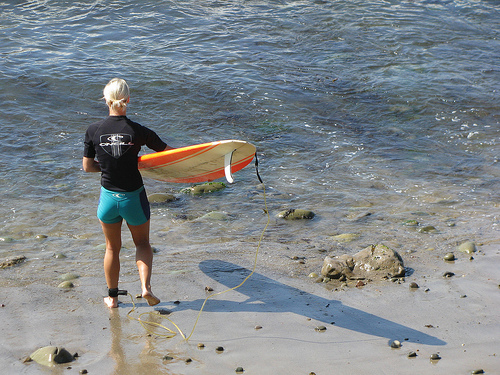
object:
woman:
[82, 78, 176, 308]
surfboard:
[137, 140, 257, 184]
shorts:
[96, 186, 152, 226]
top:
[85, 116, 170, 192]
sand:
[1, 180, 500, 374]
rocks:
[25, 342, 80, 369]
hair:
[100, 77, 131, 109]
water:
[1, 0, 498, 285]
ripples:
[0, 0, 500, 291]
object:
[106, 288, 128, 297]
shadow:
[118, 258, 446, 351]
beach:
[0, 189, 499, 373]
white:
[99, 132, 133, 158]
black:
[139, 187, 151, 219]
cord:
[128, 153, 270, 341]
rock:
[275, 207, 317, 220]